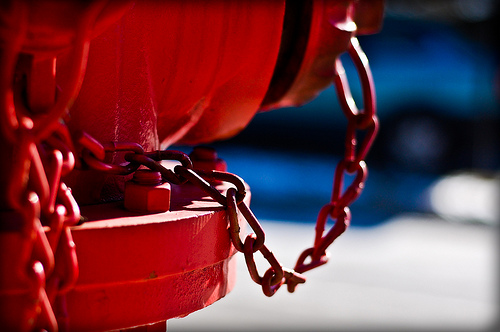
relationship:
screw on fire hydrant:
[132, 168, 160, 213] [5, 2, 397, 327]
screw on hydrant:
[132, 168, 160, 213] [11, 6, 266, 326]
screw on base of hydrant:
[122, 167, 170, 213] [5, 7, 377, 318]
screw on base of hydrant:
[185, 147, 228, 195] [5, 7, 377, 318]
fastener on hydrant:
[123, 183, 175, 208] [5, 7, 377, 318]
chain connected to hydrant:
[213, 181, 348, 306] [5, 7, 377, 318]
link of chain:
[328, 157, 371, 204] [209, 129, 406, 306]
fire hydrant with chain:
[5, 2, 397, 327] [5, 117, 81, 332]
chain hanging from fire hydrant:
[213, 181, 341, 298] [5, 2, 397, 332]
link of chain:
[314, 162, 388, 243] [5, 2, 404, 328]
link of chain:
[226, 179, 264, 250] [27, 62, 380, 258]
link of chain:
[301, 49, 409, 291] [265, 88, 404, 259]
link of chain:
[234, 225, 286, 292] [188, 103, 396, 301]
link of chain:
[184, 145, 293, 256] [298, 69, 384, 270]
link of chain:
[303, 208, 393, 276] [231, 39, 391, 296]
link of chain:
[343, 102, 383, 159] [123, 143, 384, 298]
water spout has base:
[261, 0, 385, 110] [0, 154, 246, 330]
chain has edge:
[54, 41, 432, 311] [289, 253, 309, 270]